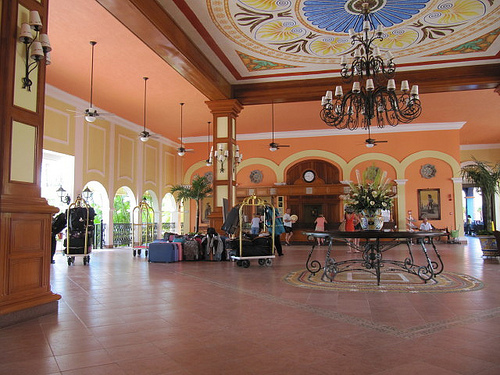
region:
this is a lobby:
[45, 5, 485, 372]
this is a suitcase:
[135, 224, 185, 271]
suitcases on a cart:
[215, 174, 305, 276]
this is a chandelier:
[294, 7, 440, 181]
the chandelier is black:
[314, 12, 442, 158]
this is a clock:
[293, 162, 330, 187]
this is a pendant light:
[73, 12, 111, 129]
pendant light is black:
[80, 27, 110, 130]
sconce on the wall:
[8, 7, 68, 107]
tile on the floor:
[73, 262, 273, 368]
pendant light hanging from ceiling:
[82, 100, 102, 134]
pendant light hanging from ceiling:
[129, 112, 150, 149]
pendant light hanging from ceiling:
[165, 133, 192, 163]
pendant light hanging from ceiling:
[200, 154, 213, 171]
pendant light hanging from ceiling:
[262, 135, 284, 163]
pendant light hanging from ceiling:
[365, 132, 375, 157]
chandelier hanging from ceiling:
[316, 72, 454, 187]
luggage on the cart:
[231, 185, 284, 279]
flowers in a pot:
[340, 163, 402, 243]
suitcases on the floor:
[150, 230, 214, 264]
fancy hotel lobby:
[0, 0, 496, 372]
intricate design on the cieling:
[175, 0, 490, 90]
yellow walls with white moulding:
[42, 81, 182, 213]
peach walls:
[180, 92, 496, 228]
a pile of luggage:
[143, 187, 280, 268]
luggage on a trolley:
[53, 187, 95, 262]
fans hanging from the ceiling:
[71, 100, 394, 162]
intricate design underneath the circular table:
[285, 248, 485, 295]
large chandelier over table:
[315, 16, 425, 144]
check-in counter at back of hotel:
[199, 174, 411, 237]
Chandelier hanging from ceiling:
[315, 3, 425, 133]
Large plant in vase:
[336, 163, 400, 232]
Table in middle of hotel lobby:
[300, 227, 447, 285]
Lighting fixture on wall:
[11, 4, 53, 95]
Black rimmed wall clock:
[300, 168, 317, 183]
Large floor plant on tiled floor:
[456, 151, 498, 260]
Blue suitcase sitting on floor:
[145, 238, 182, 266]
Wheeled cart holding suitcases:
[62, 191, 94, 267]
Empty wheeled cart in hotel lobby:
[126, 193, 155, 264]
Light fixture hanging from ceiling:
[83, 38, 99, 124]